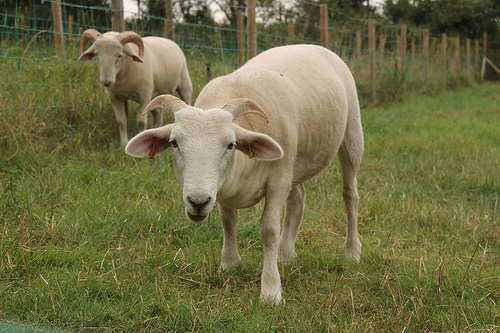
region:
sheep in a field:
[24, 16, 459, 332]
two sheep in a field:
[46, 18, 453, 278]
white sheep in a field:
[40, 19, 438, 315]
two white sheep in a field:
[34, 13, 421, 325]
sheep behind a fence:
[17, 1, 454, 276]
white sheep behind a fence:
[25, 2, 495, 257]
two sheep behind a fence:
[19, 13, 496, 246]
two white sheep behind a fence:
[33, 1, 398, 313]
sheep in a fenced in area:
[18, 8, 498, 307]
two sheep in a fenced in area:
[28, 14, 493, 289]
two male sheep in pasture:
[69, 18, 385, 313]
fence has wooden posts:
[315, 11, 484, 78]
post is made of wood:
[367, 18, 384, 100]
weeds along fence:
[382, 53, 476, 92]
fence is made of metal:
[381, 31, 426, 88]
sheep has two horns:
[127, 84, 273, 124]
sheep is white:
[116, 42, 392, 290]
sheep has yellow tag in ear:
[242, 140, 261, 165]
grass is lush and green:
[32, 190, 172, 295]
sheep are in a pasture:
[62, 14, 442, 313]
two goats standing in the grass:
[74, 26, 366, 306]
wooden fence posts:
[0, 0, 492, 109]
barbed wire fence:
[1, 2, 496, 141]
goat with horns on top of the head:
[126, 43, 368, 307]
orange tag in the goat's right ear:
[126, 43, 365, 306]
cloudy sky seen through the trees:
[121, 0, 421, 25]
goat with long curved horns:
[76, 25, 193, 148]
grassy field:
[0, 80, 499, 329]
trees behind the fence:
[0, 0, 497, 69]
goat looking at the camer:
[123, 42, 366, 302]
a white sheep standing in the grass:
[121, 40, 366, 305]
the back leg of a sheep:
[335, 151, 380, 271]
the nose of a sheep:
[173, 157, 220, 227]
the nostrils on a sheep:
[187, 193, 209, 205]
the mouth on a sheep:
[181, 206, 206, 222]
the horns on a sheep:
[136, 92, 271, 120]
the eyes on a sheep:
[167, 133, 237, 154]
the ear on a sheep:
[233, 125, 283, 166]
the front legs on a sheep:
[212, 202, 287, 305]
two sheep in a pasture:
[58, 18, 376, 313]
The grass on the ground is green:
[32, 206, 179, 314]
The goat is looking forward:
[95, 36, 410, 311]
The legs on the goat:
[215, 205, 290, 310]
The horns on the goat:
[130, 80, 270, 120]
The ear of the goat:
[115, 117, 165, 159]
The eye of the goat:
[160, 130, 185, 155]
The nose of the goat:
[181, 185, 211, 206]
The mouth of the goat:
[170, 205, 215, 226]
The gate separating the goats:
[195, 0, 471, 100]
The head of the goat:
[71, 18, 148, 89]